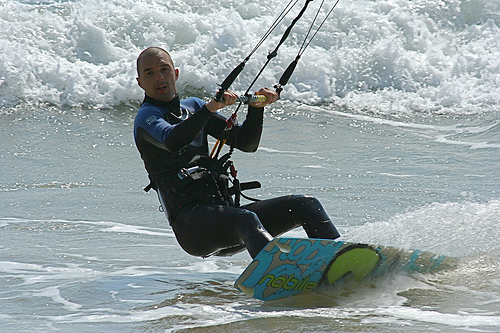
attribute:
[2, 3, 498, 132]
waves — white and gray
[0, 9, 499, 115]
waves — white and gray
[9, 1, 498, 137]
wave — large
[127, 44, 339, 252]
male — windsurfer, white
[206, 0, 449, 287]
wind surfer — male, white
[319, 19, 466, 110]
foam — in distance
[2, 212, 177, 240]
ocean wave — white and gray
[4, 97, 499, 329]
water — calm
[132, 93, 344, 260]
wetsuit — blue and black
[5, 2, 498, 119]
waves — white and gray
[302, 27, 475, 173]
ocean waves — white and gray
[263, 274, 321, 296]
writing — blue